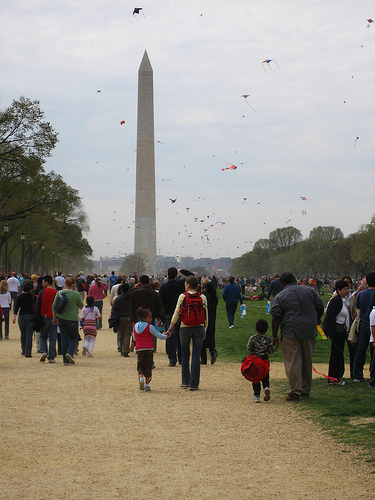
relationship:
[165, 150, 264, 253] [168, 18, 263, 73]
kites in sky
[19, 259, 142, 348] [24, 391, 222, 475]
people on walkway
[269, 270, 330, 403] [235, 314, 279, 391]
man with a kid